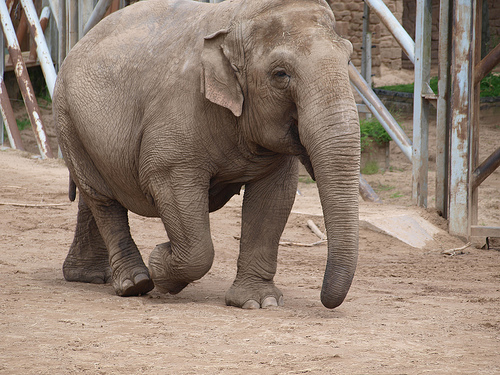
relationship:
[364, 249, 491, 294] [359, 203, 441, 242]
dirt covering sidewalk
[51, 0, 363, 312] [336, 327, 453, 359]
elephant on dirt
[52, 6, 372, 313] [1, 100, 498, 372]
elephant walking in dirt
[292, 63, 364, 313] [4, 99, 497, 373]
trunk touching ground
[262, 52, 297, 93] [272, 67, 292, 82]
wrinkle around eye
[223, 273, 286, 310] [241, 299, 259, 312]
hoof has nail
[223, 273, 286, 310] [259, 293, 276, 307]
hoof has nail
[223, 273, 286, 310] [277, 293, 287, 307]
hoof has nail